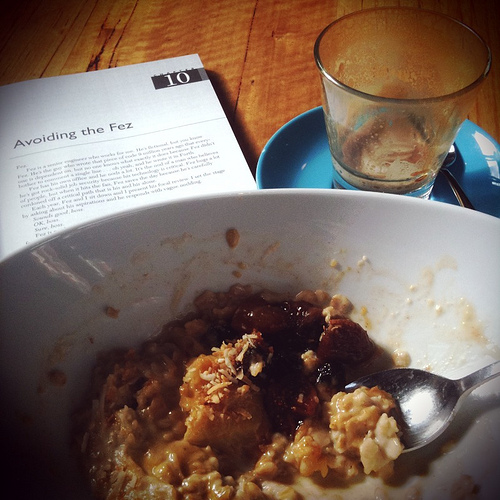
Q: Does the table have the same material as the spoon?
A: No, the table is made of wood and the spoon is made of metal.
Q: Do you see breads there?
A: No, there are no breads.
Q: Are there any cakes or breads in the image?
A: No, there are no breads or cakes.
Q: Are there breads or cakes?
A: No, there are no breads or cakes.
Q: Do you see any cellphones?
A: No, there are no cellphones.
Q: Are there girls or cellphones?
A: No, there are no cellphones or girls.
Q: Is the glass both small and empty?
A: Yes, the glass is small and empty.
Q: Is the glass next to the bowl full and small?
A: No, the glass is small but empty.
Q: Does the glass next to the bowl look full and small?
A: No, the glass is small but empty.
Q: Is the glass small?
A: Yes, the glass is small.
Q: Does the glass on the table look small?
A: Yes, the glass is small.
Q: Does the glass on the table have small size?
A: Yes, the glass is small.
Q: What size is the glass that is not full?
A: The glass is small.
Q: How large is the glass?
A: The glass is small.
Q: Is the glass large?
A: No, the glass is small.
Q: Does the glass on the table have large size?
A: No, the glass is small.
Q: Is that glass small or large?
A: The glass is small.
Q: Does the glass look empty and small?
A: Yes, the glass is empty and small.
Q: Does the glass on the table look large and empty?
A: No, the glass is empty but small.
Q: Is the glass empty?
A: Yes, the glass is empty.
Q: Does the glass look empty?
A: Yes, the glass is empty.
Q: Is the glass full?
A: No, the glass is empty.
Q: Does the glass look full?
A: No, the glass is empty.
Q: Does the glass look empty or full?
A: The glass is empty.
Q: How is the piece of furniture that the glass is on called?
A: The piece of furniture is a table.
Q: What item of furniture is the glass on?
A: The glass is on the table.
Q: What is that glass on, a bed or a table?
A: The glass is on a table.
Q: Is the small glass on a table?
A: Yes, the glass is on a table.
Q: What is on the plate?
A: The glass is on the plate.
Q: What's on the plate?
A: The glass is on the plate.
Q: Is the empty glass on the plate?
A: Yes, the glass is on the plate.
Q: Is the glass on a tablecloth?
A: No, the glass is on the plate.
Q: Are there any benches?
A: No, there are no benches.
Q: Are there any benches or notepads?
A: No, there are no benches or notepads.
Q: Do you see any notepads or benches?
A: No, there are no benches or notepads.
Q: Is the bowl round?
A: Yes, the bowl is round.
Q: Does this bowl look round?
A: Yes, the bowl is round.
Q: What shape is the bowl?
A: The bowl is round.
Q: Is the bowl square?
A: No, the bowl is round.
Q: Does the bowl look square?
A: No, the bowl is round.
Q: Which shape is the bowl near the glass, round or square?
A: The bowl is round.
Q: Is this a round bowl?
A: Yes, this is a round bowl.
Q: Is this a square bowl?
A: No, this is a round bowl.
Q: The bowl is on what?
A: The bowl is on the table.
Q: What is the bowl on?
A: The bowl is on the table.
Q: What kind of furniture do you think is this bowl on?
A: The bowl is on the table.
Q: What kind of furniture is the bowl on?
A: The bowl is on the table.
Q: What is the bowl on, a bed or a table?
A: The bowl is on a table.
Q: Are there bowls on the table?
A: Yes, there is a bowl on the table.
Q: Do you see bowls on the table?
A: Yes, there is a bowl on the table.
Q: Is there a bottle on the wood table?
A: No, there is a bowl on the table.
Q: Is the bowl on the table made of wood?
A: Yes, the bowl is on the table.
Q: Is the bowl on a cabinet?
A: No, the bowl is on the table.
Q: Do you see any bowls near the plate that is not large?
A: Yes, there is a bowl near the plate.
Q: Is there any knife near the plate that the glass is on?
A: No, there is a bowl near the plate.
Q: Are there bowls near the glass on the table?
A: Yes, there is a bowl near the glass.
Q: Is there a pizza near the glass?
A: No, there is a bowl near the glass.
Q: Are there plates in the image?
A: Yes, there is a plate.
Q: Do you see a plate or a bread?
A: Yes, there is a plate.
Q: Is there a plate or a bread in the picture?
A: Yes, there is a plate.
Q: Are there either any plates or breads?
A: Yes, there is a plate.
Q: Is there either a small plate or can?
A: Yes, there is a small plate.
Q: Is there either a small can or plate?
A: Yes, there is a small plate.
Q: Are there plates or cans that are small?
A: Yes, the plate is small.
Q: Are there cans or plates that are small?
A: Yes, the plate is small.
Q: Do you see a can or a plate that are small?
A: Yes, the plate is small.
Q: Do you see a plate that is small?
A: Yes, there is a small plate.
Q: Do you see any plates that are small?
A: Yes, there is a plate that is small.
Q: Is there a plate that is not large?
A: Yes, there is a small plate.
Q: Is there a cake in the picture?
A: No, there are no cakes.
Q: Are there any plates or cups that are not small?
A: No, there is a plate but it is small.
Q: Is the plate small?
A: Yes, the plate is small.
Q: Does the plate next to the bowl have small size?
A: Yes, the plate is small.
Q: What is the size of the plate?
A: The plate is small.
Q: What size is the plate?
A: The plate is small.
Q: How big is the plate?
A: The plate is small.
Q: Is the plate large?
A: No, the plate is small.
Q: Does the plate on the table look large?
A: No, the plate is small.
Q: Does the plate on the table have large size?
A: No, the plate is small.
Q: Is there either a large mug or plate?
A: No, there is a plate but it is small.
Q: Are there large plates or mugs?
A: No, there is a plate but it is small.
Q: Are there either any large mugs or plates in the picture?
A: No, there is a plate but it is small.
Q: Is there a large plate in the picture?
A: No, there is a plate but it is small.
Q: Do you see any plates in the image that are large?
A: No, there is a plate but it is small.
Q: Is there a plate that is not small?
A: No, there is a plate but it is small.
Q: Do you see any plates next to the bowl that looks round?
A: Yes, there is a plate next to the bowl.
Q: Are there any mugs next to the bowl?
A: No, there is a plate next to the bowl.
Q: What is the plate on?
A: The plate is on the table.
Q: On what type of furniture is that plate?
A: The plate is on the table.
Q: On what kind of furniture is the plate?
A: The plate is on the table.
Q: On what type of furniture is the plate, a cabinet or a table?
A: The plate is on a table.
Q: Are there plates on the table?
A: Yes, there is a plate on the table.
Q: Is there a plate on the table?
A: Yes, there is a plate on the table.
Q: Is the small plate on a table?
A: Yes, the plate is on a table.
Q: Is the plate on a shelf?
A: No, the plate is on a table.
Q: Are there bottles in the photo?
A: No, there are no bottles.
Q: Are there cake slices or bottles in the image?
A: No, there are no bottles or cake slices.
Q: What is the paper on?
A: The paper is on the table.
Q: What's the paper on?
A: The paper is on the table.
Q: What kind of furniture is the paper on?
A: The paper is on the table.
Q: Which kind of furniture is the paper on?
A: The paper is on the table.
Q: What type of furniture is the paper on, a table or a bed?
A: The paper is on a table.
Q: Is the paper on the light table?
A: Yes, the paper is on the table.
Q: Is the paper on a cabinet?
A: No, the paper is on the table.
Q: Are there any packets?
A: No, there are no packets.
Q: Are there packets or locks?
A: No, there are no packets or locks.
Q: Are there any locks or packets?
A: No, there are no packets or locks.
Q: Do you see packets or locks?
A: No, there are no packets or locks.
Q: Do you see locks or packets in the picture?
A: No, there are no packets or locks.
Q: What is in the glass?
A: The water is in the glass.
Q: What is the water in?
A: The water is in the glass.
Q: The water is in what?
A: The water is in the glass.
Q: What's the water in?
A: The water is in the glass.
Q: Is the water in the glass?
A: Yes, the water is in the glass.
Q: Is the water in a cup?
A: No, the water is in the glass.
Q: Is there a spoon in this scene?
A: Yes, there is a spoon.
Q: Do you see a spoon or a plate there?
A: Yes, there is a spoon.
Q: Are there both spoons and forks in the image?
A: No, there is a spoon but no forks.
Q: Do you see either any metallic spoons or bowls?
A: Yes, there is a metal spoon.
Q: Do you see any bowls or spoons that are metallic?
A: Yes, the spoon is metallic.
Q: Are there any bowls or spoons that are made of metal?
A: Yes, the spoon is made of metal.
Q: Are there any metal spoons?
A: Yes, there is a metal spoon.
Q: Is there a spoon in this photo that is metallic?
A: Yes, there is a spoon that is metallic.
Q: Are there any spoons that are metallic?
A: Yes, there is a spoon that is metallic.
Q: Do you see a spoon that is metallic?
A: Yes, there is a spoon that is metallic.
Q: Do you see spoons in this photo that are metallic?
A: Yes, there is a spoon that is metallic.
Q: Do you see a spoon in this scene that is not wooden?
A: Yes, there is a metallic spoon.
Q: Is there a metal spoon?
A: Yes, there is a spoon that is made of metal.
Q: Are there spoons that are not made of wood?
A: Yes, there is a spoon that is made of metal.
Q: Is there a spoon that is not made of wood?
A: Yes, there is a spoon that is made of metal.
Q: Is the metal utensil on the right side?
A: Yes, the spoon is on the right of the image.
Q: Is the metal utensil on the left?
A: No, the spoon is on the right of the image.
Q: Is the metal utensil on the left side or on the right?
A: The spoon is on the right of the image.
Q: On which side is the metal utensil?
A: The spoon is on the right of the image.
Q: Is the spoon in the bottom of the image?
A: Yes, the spoon is in the bottom of the image.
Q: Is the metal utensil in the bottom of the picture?
A: Yes, the spoon is in the bottom of the image.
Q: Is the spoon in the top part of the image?
A: No, the spoon is in the bottom of the image.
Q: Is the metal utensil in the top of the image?
A: No, the spoon is in the bottom of the image.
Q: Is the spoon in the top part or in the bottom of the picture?
A: The spoon is in the bottom of the image.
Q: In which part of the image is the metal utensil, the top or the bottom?
A: The spoon is in the bottom of the image.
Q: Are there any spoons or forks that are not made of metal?
A: No, there is a spoon but it is made of metal.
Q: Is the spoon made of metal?
A: Yes, the spoon is made of metal.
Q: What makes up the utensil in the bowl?
A: The spoon is made of metal.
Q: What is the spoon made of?
A: The spoon is made of metal.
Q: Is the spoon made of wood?
A: No, the spoon is made of metal.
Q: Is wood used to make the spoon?
A: No, the spoon is made of metal.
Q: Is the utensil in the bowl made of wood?
A: No, the spoon is made of metal.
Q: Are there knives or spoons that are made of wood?
A: No, there is a spoon but it is made of metal.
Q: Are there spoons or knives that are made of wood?
A: No, there is a spoon but it is made of metal.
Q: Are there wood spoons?
A: No, there is a spoon but it is made of metal.